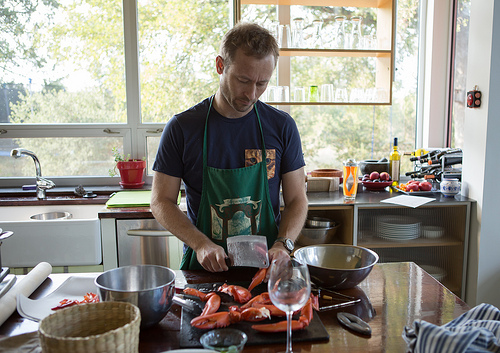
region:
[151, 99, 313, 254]
Man is wearing blue shirt.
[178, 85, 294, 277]
Man is wearing green apron.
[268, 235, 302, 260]
Man is wearing watch.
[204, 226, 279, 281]
Man is holding meat cleaver.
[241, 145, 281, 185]
Cat on shirt pocket.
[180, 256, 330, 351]
Lobster claws on cutting board.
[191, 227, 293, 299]
Man is cracking lobster claw.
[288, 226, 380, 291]
Stainless steel bowl on work island.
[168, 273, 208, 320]
Tongs laying on cutting board edge.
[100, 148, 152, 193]
Scraggly plant in orange flower pot.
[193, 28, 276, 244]
a man wearing a green apron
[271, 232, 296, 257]
a man has a watch on his left wrist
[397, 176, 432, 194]
red tomatoes are on the counter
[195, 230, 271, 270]
man has a clever that is upside down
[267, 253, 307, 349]
a wine glass is on the counter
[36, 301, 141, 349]
a basket is on the counter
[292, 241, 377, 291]
a stainless steel bowl is on the table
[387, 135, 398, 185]
a bottle of wine is near the window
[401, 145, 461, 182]
the wine rack is filled with bottles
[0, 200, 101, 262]
a bowl is in the kitchen sink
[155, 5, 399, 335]
man cooking lobster in kitchen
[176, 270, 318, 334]
lobster on kitchen counter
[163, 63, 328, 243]
man wearing green apron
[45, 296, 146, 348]
straw basket on counter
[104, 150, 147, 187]
red pot on counter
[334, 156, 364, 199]
bottle of detergent on shelf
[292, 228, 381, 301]
stainless bowl on counter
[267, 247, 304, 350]
wine glass on counter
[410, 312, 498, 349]
striped kitchen towel on counter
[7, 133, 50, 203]
stainless kitchen faucet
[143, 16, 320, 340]
a man is chopping a lobster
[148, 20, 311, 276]
man is using a butchers cleaver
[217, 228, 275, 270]
meat cleaver is upside down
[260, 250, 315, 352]
wine glass in the foreground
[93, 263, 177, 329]
stainless steel mixing bowl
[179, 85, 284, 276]
a green apron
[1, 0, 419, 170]
trees outside a window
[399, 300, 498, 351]
a striped tea towel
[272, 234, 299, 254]
watch on a mans left wrist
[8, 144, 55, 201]
stainless steel tap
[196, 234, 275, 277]
Man is holding cleaver.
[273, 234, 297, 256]
Man is wearing a watch.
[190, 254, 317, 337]
Man is cleaning lobster.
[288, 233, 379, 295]
Stainless steel bowl next to man's arm.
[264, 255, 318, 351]
Empty wine glass on counter.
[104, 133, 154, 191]
Potted plant by window.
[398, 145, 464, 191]
Bottles of wine in rack.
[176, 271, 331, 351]
Lobster laying on cutting board.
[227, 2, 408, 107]
Glasses on shelves on rack by window.